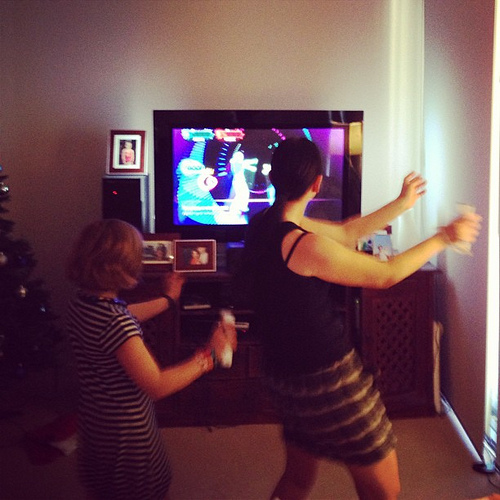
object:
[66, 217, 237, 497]
girl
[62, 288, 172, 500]
striped dress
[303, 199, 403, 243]
arm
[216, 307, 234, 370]
controller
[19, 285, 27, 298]
ornament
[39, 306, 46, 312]
ornament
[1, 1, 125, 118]
wall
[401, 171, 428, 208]
hand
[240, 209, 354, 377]
shirt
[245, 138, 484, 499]
lady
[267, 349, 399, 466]
skirt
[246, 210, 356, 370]
tank top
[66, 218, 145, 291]
hair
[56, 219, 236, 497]
person game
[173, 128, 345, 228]
game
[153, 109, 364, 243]
television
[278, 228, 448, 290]
arm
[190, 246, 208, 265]
two people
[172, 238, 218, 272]
frame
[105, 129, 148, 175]
picture frames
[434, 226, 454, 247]
strap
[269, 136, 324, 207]
head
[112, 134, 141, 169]
picture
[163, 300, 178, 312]
band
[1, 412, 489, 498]
beige carpet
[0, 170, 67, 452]
tree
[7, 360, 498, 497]
floor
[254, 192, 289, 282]
pony tail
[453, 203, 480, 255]
controller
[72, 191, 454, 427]
media center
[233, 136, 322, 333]
hair